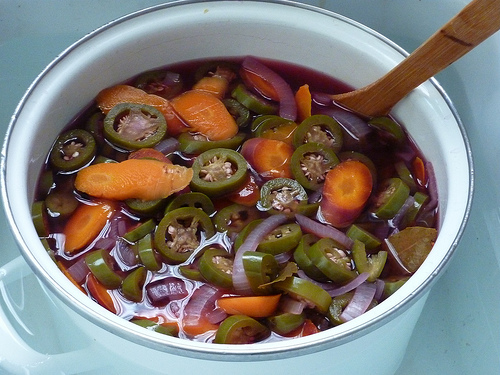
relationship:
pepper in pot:
[191, 144, 251, 197] [10, 9, 481, 361]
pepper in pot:
[100, 90, 168, 150] [10, 9, 481, 361]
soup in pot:
[74, 68, 395, 301] [10, 9, 481, 361]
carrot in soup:
[62, 202, 117, 253] [74, 68, 395, 301]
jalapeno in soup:
[287, 103, 344, 182] [74, 68, 395, 301]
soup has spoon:
[74, 68, 395, 301] [324, 8, 497, 118]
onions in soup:
[297, 203, 355, 254] [74, 68, 395, 301]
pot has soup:
[10, 9, 481, 361] [74, 68, 395, 301]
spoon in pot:
[324, 8, 497, 118] [10, 9, 481, 361]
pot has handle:
[10, 9, 481, 361] [5, 263, 76, 354]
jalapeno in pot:
[287, 103, 344, 182] [10, 9, 481, 361]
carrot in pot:
[62, 202, 117, 253] [10, 9, 481, 361]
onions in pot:
[297, 203, 355, 254] [10, 9, 481, 361]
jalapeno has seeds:
[287, 103, 344, 182] [307, 154, 325, 170]